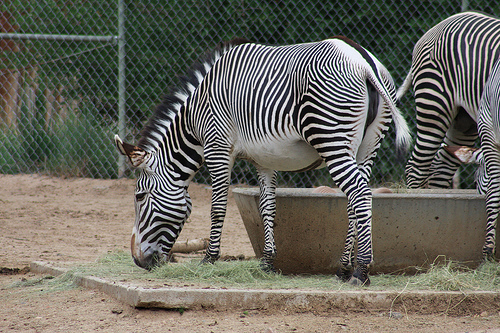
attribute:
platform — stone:
[29, 248, 496, 318]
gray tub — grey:
[283, 185, 479, 272]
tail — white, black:
[358, 42, 422, 162]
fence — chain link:
[0, 0, 485, 184]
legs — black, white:
[303, 134, 374, 278]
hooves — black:
[338, 260, 380, 292]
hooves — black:
[329, 256, 352, 281]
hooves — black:
[252, 252, 269, 276]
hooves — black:
[189, 247, 226, 269]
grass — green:
[77, 255, 499, 287]